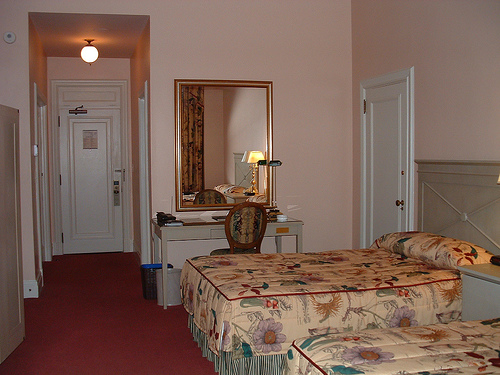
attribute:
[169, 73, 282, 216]
mirror — large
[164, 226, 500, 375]
bed — queen size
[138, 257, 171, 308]
garbage can — black, white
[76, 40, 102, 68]
light — turned on, globe, bright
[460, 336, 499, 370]
flower — purple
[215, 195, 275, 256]
chair — wood, brown, small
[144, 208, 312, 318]
desk — white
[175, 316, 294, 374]
skirt — strip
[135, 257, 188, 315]
waste baskets — next to each other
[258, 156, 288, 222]
desk lamp — gold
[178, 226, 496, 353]
bed — multi coloured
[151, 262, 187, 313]
wastebasket — white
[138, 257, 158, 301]
wastebasket — blue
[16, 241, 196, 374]
carpet — red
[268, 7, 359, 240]
wall — light pink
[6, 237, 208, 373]
carpet — red